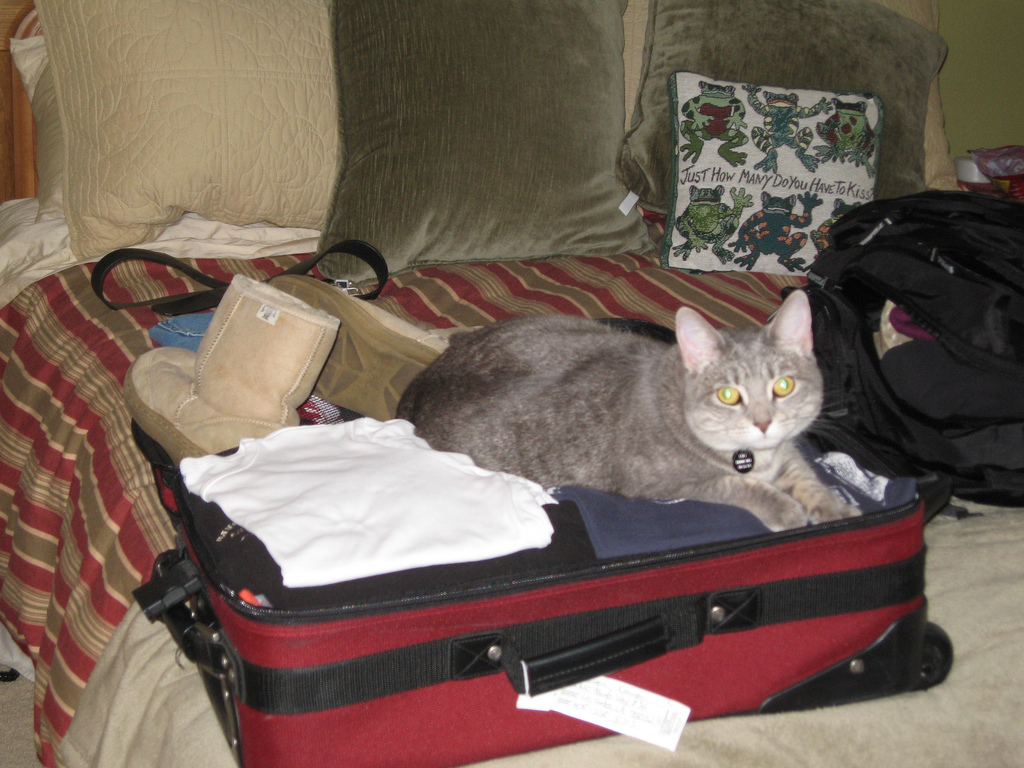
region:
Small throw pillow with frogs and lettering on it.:
[660, 67, 888, 282]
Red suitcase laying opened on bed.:
[133, 489, 955, 766]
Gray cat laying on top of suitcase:
[389, 282, 876, 548]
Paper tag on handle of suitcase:
[508, 655, 696, 755]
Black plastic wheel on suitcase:
[868, 604, 960, 702]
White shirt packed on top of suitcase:
[170, 416, 569, 593]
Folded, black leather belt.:
[81, 229, 395, 318]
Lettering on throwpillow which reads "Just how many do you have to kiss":
[672, 159, 879, 211]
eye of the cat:
[775, 373, 814, 403]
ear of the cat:
[678, 315, 707, 366]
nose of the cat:
[753, 417, 779, 433]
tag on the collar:
[706, 443, 765, 481]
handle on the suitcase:
[538, 629, 649, 683]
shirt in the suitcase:
[516, 559, 552, 567]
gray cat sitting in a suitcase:
[229, 268, 910, 766]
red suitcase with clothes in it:
[168, 444, 938, 767]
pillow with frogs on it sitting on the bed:
[614, 64, 937, 283]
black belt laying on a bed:
[95, 229, 391, 328]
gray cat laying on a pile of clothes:
[393, 279, 877, 568]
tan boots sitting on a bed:
[130, 268, 451, 461]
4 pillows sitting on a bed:
[51, 0, 981, 256]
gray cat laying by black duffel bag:
[392, 188, 1021, 533]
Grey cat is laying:
[396, 288, 843, 533]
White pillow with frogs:
[659, 72, 891, 273]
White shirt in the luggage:
[178, 414, 555, 586]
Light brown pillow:
[35, 0, 342, 264]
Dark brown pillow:
[317, 0, 651, 286]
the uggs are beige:
[125, 274, 449, 468]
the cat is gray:
[394, 284, 859, 528]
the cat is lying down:
[394, 287, 856, 528]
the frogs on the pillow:
[661, 69, 884, 275]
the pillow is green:
[314, 2, 656, 278]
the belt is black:
[93, 236, 388, 319]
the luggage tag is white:
[514, 653, 692, 753]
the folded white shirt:
[175, 414, 558, 589]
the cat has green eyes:
[394, 290, 854, 531]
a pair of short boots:
[116, 252, 478, 467]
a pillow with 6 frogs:
[666, 63, 894, 294]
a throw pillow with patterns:
[24, 0, 358, 253]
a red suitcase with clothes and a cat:
[107, 370, 973, 740]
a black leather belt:
[84, 236, 417, 316]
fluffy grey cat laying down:
[393, 287, 847, 538]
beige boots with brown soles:
[121, 265, 482, 462]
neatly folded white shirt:
[179, 414, 557, 592]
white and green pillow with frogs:
[658, 66, 887, 278]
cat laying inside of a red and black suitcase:
[121, 287, 951, 766]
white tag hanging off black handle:
[488, 612, 691, 753]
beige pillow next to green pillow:
[35, 0, 652, 285]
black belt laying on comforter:
[83, 237, 388, 321]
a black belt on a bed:
[92, 237, 390, 307]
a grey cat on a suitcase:
[414, 282, 854, 526]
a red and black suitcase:
[159, 516, 981, 763]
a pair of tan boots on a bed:
[133, 281, 466, 440]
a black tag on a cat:
[721, 447, 760, 477]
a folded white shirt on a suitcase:
[180, 418, 547, 574]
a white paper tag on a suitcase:
[513, 655, 695, 760]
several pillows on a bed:
[22, 13, 918, 290]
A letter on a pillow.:
[685, 160, 693, 187]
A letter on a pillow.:
[692, 168, 697, 182]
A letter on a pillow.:
[701, 165, 706, 178]